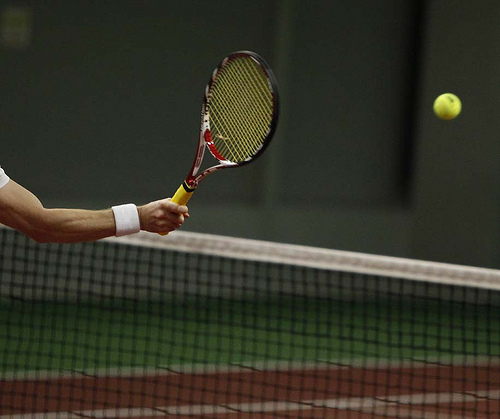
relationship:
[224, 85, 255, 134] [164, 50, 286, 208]
strings are attached to racket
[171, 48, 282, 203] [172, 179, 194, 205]
racket has handle